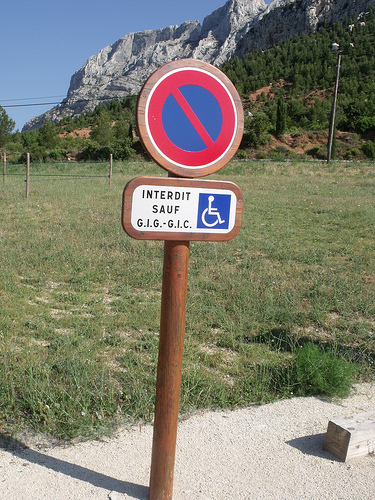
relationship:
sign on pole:
[122, 176, 245, 242] [150, 169, 192, 498]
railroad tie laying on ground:
[324, 413, 375, 462] [211, 387, 373, 499]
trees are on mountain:
[22, 24, 374, 160] [22, 2, 374, 154]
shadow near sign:
[1, 428, 152, 499] [120, 58, 245, 497]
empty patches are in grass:
[34, 278, 131, 373] [2, 162, 372, 446]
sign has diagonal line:
[137, 57, 247, 176] [168, 85, 216, 148]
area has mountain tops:
[4, 0, 373, 158] [67, 4, 375, 102]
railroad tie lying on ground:
[324, 413, 375, 462] [211, 387, 373, 499]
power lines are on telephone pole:
[2, 60, 374, 111] [327, 52, 343, 159]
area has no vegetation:
[248, 76, 285, 104] [22, 24, 374, 160]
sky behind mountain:
[0, 1, 277, 132] [22, 2, 374, 154]